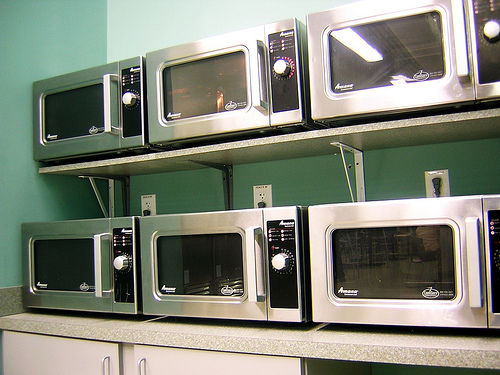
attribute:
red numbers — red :
[259, 50, 312, 85]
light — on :
[160, 50, 261, 140]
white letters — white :
[160, 104, 198, 123]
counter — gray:
[6, 295, 495, 360]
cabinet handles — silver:
[93, 352, 155, 372]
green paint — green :
[8, 170, 52, 210]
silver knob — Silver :
[265, 234, 294, 275]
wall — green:
[3, 0, 184, 73]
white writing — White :
[335, 281, 365, 299]